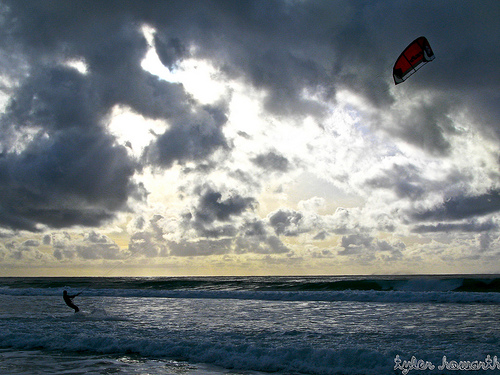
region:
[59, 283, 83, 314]
a person driving in water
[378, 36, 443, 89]
a object in the air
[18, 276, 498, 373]
beautiful view of a water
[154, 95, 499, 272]
a beautiful white sky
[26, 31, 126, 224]
a beautiful black clouds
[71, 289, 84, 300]
the hand of a person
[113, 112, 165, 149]
gap in between clouds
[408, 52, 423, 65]
a small design in the object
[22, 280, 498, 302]
a small flow of water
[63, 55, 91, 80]
a small gap in the sky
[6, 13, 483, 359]
the sky is overcast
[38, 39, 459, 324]
this guy is parasailing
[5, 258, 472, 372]
the water if fairly calm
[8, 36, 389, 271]
the clouds look amazing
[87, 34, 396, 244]
sunlight is trying to break through the clouds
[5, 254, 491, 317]
yellow light over the horizon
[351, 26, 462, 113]
an orange or red parasail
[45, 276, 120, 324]
the surfer can barely be seen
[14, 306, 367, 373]
the water is wavey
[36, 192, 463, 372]
this scene looks refreshing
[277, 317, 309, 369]
The water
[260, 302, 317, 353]
The water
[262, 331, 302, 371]
The water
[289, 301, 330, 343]
The water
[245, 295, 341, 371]
The water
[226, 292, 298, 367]
The water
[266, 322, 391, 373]
The beach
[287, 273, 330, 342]
The beach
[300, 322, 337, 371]
The beach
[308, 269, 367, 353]
The beach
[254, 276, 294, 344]
The beach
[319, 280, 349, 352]
The beach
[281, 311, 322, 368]
The beach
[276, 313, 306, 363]
The beach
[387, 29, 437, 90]
a red and black parasail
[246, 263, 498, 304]
wavea rolling into shore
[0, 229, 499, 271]
Light os the sun just below the horizon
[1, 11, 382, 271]
thickening clouds coming in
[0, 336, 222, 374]
shallowest water nearest the beach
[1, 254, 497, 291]
the distant horizon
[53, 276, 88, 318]
parasailer pulling in the sail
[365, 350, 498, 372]
the name of the photographer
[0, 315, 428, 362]
edge of the wave hitting the shore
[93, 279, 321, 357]
light reflecting off the water